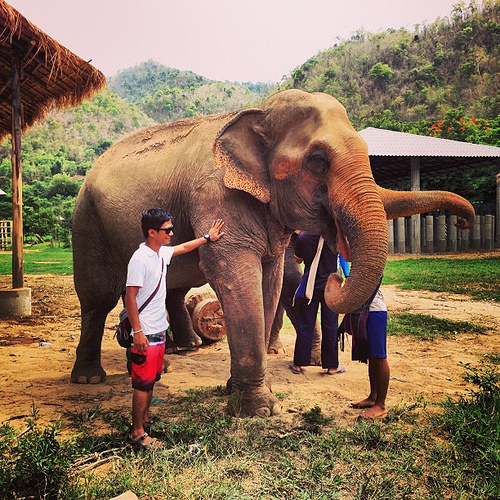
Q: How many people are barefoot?
A: 1.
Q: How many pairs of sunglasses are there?
A: 1.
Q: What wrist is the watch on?
A: Left.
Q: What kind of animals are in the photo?
A: Elephants.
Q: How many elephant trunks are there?
A: 2.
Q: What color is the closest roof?
A: Brown.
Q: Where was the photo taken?
A: In the jungle.